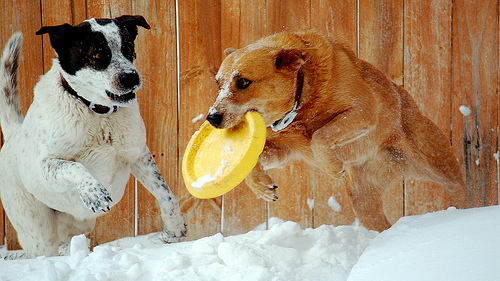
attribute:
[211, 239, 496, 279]
snow — white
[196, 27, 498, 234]
dog — white , brown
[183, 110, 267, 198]
disc — yellow 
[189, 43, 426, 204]
dog — Brown 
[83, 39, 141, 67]
eyes — white 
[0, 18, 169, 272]
dog — black, White 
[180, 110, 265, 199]
frisbee — yellow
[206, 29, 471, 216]
dog — Brown 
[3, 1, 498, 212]
fence — wood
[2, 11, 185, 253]
dog — White , black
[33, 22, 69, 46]
ear — black